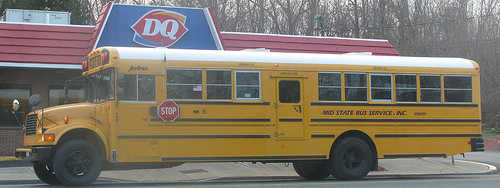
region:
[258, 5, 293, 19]
the sky through the trees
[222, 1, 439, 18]
the trees behind the building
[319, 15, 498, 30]
a wire behind the building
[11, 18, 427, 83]
a red building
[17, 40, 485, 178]
a yellow bus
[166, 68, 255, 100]
windows on the bus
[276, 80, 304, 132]
a door on the bus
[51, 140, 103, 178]
a tire on the bus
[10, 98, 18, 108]
a mirror on the bus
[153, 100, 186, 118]
the stop sign on the bus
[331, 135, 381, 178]
rear left tire on bus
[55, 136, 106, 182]
front left tire on bus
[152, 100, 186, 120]
red stop sign on bus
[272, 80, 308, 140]
door on side of bus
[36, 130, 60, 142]
lights on front of bus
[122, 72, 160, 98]
driver's window on bus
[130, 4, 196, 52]
dairy queen logo on building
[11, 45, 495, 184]
yellow school bus in front of building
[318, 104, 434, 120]
black print on bus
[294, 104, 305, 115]
handle on the door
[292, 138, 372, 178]
the back wheels of a bus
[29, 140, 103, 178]
the front wheels of a bus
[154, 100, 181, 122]
the stop sign on a bus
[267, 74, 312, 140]
the emergency door of the bus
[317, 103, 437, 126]
writing on the side of the bus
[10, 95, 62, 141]
the headlights and mirrors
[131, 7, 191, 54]
a dairy queen sign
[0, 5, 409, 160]
a dairy queen restaurant behind the bus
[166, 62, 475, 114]
windows on the side of the bus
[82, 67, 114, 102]
the front windshield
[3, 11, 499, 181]
a big yellow bus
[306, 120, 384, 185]
the back left tire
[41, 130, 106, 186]
the front left tire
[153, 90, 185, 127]
the stop sign on bus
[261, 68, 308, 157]
a emergency door on bus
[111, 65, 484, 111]
a row of window on bus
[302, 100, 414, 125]
black writting on the bus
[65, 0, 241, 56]
a DQ sign on a building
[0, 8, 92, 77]
part of a red roof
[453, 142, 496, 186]
a concrete curb behind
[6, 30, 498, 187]
yellow school bus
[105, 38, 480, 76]
top of the bus is white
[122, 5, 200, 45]
Dairy Queen logo on the top of the building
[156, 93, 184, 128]
red and white stop sign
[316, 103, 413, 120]
black writing on the side of the bus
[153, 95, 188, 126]
stop sign on the side of the bus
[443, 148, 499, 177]
yellow line around the edge of the sidewalk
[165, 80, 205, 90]
white bar on the window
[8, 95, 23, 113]
small mirror on the front of the bus